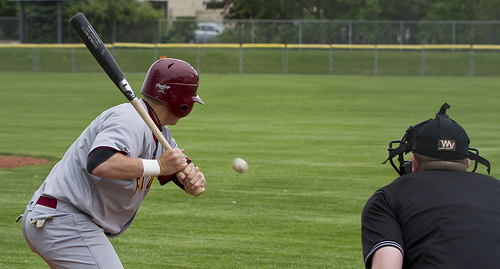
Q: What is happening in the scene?
A: Baseball game.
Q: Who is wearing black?
A: Umpire.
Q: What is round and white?
A: Baseball.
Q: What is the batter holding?
A: A bat.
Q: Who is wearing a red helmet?
A: Batter.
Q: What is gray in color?
A: Batter's uniform.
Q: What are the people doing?
A: Playing baseball.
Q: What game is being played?
A: Baseball.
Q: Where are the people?
A: On a baseball field.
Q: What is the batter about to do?
A: Hit a ball.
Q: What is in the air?
A: A ball.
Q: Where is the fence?
A: At the back of the field.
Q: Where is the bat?
A: In the batter's hands.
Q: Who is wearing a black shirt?
A: Catcher.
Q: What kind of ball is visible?
A: Baseball.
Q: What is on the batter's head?
A: Helmet.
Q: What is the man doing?
A: Hitting the baseball.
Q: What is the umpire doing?
A: Watching the pitch.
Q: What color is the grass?
A: Green.